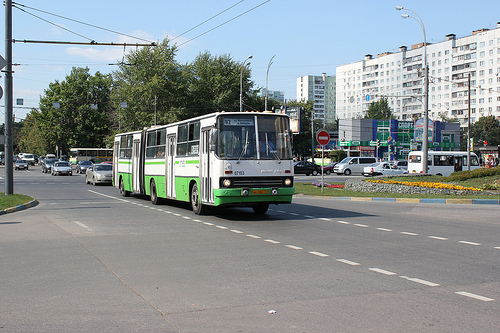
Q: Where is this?
A: This is at the street.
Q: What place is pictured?
A: It is a street.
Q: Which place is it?
A: It is a street.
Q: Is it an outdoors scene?
A: Yes, it is outdoors.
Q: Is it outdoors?
A: Yes, it is outdoors.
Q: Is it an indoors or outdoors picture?
A: It is outdoors.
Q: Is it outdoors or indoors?
A: It is outdoors.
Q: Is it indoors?
A: No, it is outdoors.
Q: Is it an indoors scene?
A: No, it is outdoors.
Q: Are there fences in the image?
A: No, there are no fences.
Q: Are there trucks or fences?
A: No, there are no fences or trucks.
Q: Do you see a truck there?
A: No, there are no trucks.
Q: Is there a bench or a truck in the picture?
A: No, there are no trucks or benches.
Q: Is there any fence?
A: No, there are no fences.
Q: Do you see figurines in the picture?
A: No, there are no figurines.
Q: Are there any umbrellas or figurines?
A: No, there are no figurines or umbrellas.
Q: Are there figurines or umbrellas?
A: No, there are no figurines or umbrellas.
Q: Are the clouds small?
A: Yes, the clouds are small.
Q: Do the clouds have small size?
A: Yes, the clouds are small.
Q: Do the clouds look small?
A: Yes, the clouds are small.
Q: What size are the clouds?
A: The clouds are small.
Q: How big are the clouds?
A: The clouds are small.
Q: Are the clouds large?
A: No, the clouds are small.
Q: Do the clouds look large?
A: No, the clouds are small.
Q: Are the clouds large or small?
A: The clouds are small.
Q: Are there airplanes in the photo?
A: No, there are no airplanes.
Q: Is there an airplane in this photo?
A: No, there are no airplanes.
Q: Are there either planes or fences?
A: No, there are no planes or fences.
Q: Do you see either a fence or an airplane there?
A: No, there are no airplanes or fences.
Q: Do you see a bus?
A: Yes, there are buses.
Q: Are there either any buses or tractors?
A: Yes, there are buses.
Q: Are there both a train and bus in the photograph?
A: No, there are buses but no trains.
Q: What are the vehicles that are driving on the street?
A: The vehicles are buses.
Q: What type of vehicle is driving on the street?
A: The vehicles are buses.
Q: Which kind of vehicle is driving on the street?
A: The vehicles are buses.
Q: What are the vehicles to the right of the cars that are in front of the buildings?
A: The vehicles are buses.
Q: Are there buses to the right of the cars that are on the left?
A: Yes, there are buses to the right of the cars.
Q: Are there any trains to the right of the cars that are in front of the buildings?
A: No, there are buses to the right of the cars.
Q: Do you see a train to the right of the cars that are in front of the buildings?
A: No, there are buses to the right of the cars.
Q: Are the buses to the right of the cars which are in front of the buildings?
A: Yes, the buses are to the right of the cars.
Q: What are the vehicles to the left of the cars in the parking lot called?
A: The vehicles are buses.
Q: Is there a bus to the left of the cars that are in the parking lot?
A: Yes, there are buses to the left of the cars.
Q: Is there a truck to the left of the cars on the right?
A: No, there are buses to the left of the cars.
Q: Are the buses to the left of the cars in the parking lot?
A: Yes, the buses are to the left of the cars.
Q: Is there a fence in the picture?
A: No, there are no fences.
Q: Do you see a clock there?
A: No, there are no clocks.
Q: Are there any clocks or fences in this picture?
A: No, there are no clocks or fences.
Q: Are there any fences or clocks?
A: No, there are no clocks or fences.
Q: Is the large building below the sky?
A: Yes, the building is below the sky.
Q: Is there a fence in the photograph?
A: No, there are no fences.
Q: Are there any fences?
A: No, there are no fences.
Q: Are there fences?
A: No, there are no fences.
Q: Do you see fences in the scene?
A: No, there are no fences.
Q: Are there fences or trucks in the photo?
A: No, there are no fences or trucks.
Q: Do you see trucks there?
A: No, there are no trucks.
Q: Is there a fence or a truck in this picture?
A: No, there are no trucks or fences.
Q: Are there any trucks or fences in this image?
A: No, there are no trucks or fences.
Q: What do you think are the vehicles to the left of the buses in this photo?
A: The vehicles are cars.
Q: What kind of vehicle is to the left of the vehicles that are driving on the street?
A: The vehicles are cars.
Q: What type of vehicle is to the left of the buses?
A: The vehicles are cars.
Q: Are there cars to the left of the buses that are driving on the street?
A: Yes, there are cars to the left of the buses.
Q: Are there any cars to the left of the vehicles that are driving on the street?
A: Yes, there are cars to the left of the buses.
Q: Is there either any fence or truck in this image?
A: No, there are no fences or trucks.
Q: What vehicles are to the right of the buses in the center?
A: The vehicles are cars.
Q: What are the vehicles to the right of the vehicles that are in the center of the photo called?
A: The vehicles are cars.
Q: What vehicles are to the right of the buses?
A: The vehicles are cars.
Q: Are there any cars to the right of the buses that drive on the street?
A: Yes, there are cars to the right of the buses.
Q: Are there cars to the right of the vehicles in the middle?
A: Yes, there are cars to the right of the buses.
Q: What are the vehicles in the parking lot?
A: The vehicles are cars.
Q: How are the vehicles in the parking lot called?
A: The vehicles are cars.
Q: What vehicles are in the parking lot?
A: The vehicles are cars.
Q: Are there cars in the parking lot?
A: Yes, there are cars in the parking lot.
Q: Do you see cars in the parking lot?
A: Yes, there are cars in the parking lot.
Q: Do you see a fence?
A: No, there are no fences.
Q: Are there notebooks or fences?
A: No, there are no fences or notebooks.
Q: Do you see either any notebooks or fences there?
A: No, there are no fences or notebooks.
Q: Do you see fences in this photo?
A: No, there are no fences.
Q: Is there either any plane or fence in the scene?
A: No, there are no fences or airplanes.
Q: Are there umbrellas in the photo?
A: No, there are no umbrellas.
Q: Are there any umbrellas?
A: No, there are no umbrellas.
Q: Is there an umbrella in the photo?
A: No, there are no umbrellas.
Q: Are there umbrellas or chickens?
A: No, there are no umbrellas or chickens.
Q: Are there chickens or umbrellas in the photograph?
A: No, there are no umbrellas or chickens.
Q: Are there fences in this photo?
A: No, there are no fences.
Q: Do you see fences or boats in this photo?
A: No, there are no fences or boats.